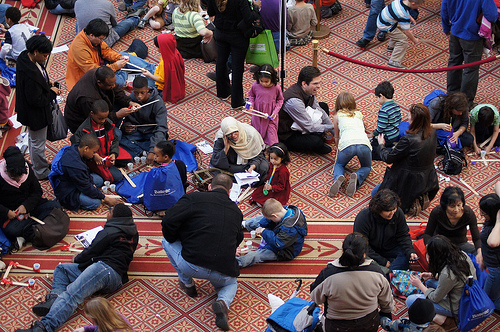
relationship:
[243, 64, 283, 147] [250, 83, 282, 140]
girl wearing dress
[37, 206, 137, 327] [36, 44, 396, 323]
man laying on floor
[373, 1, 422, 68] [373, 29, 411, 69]
boy wearing pants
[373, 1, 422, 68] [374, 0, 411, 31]
boy wearing shirt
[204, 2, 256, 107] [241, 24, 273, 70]
woman holding bag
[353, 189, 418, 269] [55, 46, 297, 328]
person in groups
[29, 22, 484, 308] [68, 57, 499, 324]
people in groups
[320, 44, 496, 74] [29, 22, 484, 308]
red rope near people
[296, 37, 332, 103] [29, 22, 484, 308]
barrier near people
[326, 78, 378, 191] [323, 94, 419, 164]
girl has shirt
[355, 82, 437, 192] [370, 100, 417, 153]
boy has shirt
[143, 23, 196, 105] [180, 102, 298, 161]
boys has coat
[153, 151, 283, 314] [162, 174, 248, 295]
man has coat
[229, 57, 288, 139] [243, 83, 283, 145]
girl has dress